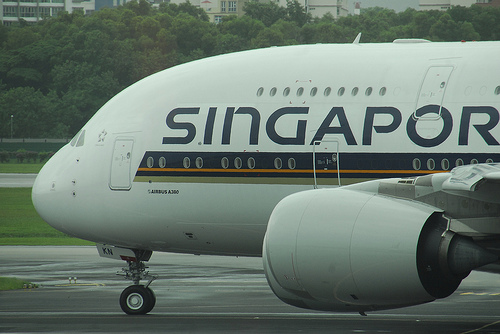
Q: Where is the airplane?
A: In an airport.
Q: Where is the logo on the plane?
A: On the side.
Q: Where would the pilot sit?
A: In the nose of the plane.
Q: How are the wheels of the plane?
A: Down.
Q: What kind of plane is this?
A: Passenger plane.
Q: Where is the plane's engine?
A: Under the logo.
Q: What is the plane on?
A: Runway.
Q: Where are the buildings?
A: Behind the trees.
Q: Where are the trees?
A: Behind the plane.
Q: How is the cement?
A: Wet.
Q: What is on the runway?
A: An airplane.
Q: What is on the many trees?
A: Green leaves.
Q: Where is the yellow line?
A: On the side of the plane.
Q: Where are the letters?
A: On the side of the plane.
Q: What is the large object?
A: An airplane.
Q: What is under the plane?
A: The front wheel.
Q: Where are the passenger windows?
A: On the side.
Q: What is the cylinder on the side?
A: The engine.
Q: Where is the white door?
A: In the front.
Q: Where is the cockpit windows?
A: In the front of the plane.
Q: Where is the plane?
A: On the runway.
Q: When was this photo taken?
A: Daytime.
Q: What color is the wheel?
A: Black.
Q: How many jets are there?
A: One.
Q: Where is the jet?
A: On the ground.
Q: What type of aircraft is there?
A: Jet.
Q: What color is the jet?
A: White.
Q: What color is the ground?
A: Grey.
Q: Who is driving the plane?
A: The captain.